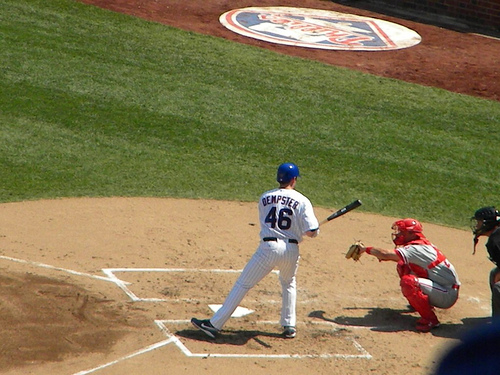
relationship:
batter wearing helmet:
[230, 169, 330, 348] [275, 162, 304, 181]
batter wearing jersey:
[230, 169, 330, 348] [254, 199, 305, 297]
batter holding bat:
[230, 169, 330, 348] [335, 196, 368, 226]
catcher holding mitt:
[376, 218, 457, 326] [346, 239, 366, 264]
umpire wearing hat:
[474, 209, 499, 287] [477, 206, 497, 231]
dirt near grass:
[425, 41, 458, 72] [102, 34, 200, 121]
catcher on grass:
[376, 218, 457, 326] [102, 34, 200, 121]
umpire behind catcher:
[474, 209, 499, 287] [376, 218, 457, 326]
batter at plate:
[230, 169, 330, 348] [215, 297, 248, 328]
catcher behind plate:
[376, 218, 457, 326] [215, 297, 248, 328]